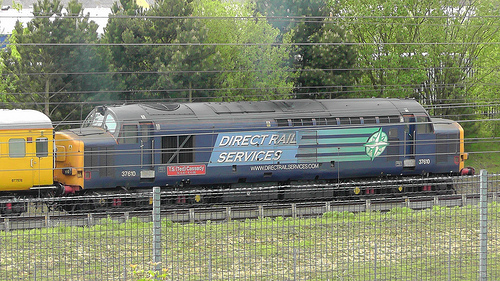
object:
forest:
[0, 2, 492, 118]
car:
[0, 105, 61, 194]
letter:
[219, 136, 230, 146]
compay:
[217, 134, 296, 163]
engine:
[59, 98, 475, 190]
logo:
[364, 128, 389, 162]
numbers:
[427, 159, 430, 164]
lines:
[106, 90, 147, 93]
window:
[123, 125, 138, 143]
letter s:
[217, 152, 228, 162]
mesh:
[340, 225, 443, 281]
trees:
[12, 0, 58, 107]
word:
[219, 135, 269, 146]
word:
[268, 133, 297, 144]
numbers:
[127, 171, 131, 177]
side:
[85, 125, 462, 188]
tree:
[298, 23, 358, 99]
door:
[402, 114, 417, 159]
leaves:
[227, 36, 231, 40]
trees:
[59, 2, 121, 109]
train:
[0, 101, 477, 222]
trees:
[186, 0, 298, 101]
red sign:
[165, 164, 207, 176]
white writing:
[187, 172, 195, 174]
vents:
[277, 119, 289, 126]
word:
[215, 150, 284, 163]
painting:
[317, 127, 380, 163]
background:
[3, 0, 498, 98]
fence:
[0, 194, 151, 278]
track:
[9, 219, 81, 229]